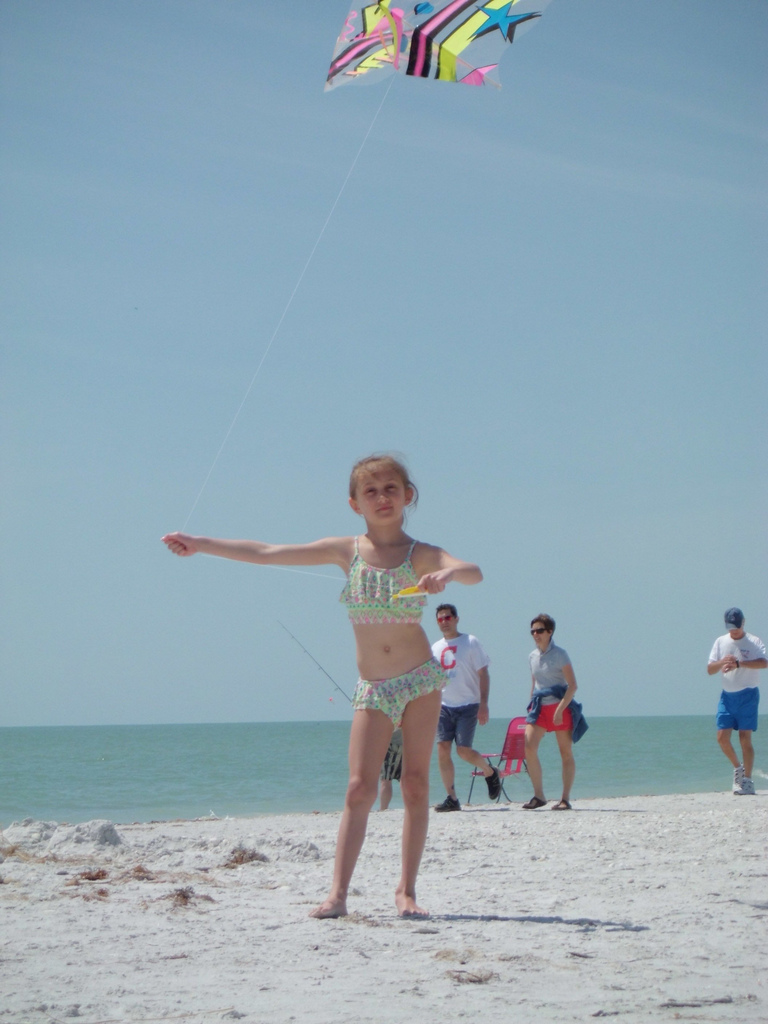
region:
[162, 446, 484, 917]
the girl wearing the bikini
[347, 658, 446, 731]
the colorful bikini bottom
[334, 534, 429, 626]
the colorful bikini top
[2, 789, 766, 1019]
the sand is beige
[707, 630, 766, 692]
the shirt is white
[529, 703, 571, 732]
the shorts are red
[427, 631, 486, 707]
the red c on the shirt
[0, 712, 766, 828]
the water is green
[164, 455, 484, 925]
A little girl in a swimsuit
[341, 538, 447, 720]
A green swimsuit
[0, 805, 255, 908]
Lumps of sand on the beach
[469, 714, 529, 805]
A pink chair on the beach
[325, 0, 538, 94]
A colorful kite flying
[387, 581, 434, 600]
String on a yellow holder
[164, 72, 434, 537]
String connecting to the kite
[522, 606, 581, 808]
A woman walking on the beach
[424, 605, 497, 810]
A man walking on the beach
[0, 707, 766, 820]
Water behind the people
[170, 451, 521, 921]
Little girl flying kite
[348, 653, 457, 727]
Little girl's bikini bottom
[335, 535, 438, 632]
Little girl's bikini top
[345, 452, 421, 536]
Face of the girl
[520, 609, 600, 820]
Woman walking on beach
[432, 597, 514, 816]
Man walking on the beach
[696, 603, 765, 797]
Man walking on the beach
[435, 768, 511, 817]
Men's black walking sneakers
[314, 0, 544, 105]
Pink, blue, and yellow kite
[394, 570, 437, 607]
yellow kite string device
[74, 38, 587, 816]
this is a beach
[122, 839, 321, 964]
the beach is sandy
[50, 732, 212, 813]
this is the ocean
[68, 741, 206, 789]
the ocean is blue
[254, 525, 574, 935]
the girl is posing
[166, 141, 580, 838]
the girl is holding a kite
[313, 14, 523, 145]
the kite is pink and yellow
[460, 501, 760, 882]
the people are walking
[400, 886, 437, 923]
foot of the person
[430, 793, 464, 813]
foot of the person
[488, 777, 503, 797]
foot of the person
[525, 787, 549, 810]
foot of the person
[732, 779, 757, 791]
foot of the person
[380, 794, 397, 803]
foot of the person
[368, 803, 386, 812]
foot of the person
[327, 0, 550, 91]
A high kite with stars on it.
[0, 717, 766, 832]
A blue body of water.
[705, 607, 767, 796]
Man in blue shorts and blue hat.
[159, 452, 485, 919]
Brown haired girl in 2 piece bathing suit.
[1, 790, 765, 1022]
A light tan colored sandy beach.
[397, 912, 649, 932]
Dark shadow of a small girl on the beach.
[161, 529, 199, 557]
A girls right hand holding a string.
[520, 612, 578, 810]
Brown haired woman in red shorts.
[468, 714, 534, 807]
A mostly pink beach chair.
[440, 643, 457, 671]
A large red letter C.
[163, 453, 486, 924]
little girl in two piece bathing suit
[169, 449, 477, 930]
little girl flies her kite on the beach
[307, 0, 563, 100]
bright colored kite in yellow, pink and blue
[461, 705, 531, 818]
red chair sits on the beach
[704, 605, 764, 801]
man wearing blue shorts with a white shirt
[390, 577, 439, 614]
yellow holder for kite string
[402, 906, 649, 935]
shadow on gils on the beach